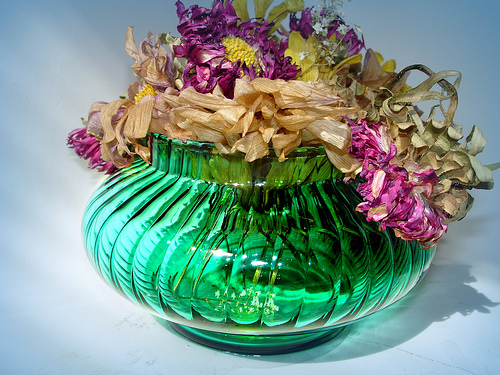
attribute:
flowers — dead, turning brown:
[87, 77, 360, 175]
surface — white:
[2, 126, 497, 371]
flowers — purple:
[182, 6, 299, 88]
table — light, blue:
[0, 188, 79, 364]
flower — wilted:
[59, 96, 142, 181]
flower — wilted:
[176, 2, 291, 92]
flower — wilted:
[339, 111, 435, 252]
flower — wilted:
[125, 30, 190, 120]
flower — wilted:
[298, 16, 365, 96]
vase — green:
[51, 85, 440, 363]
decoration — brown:
[88, 25, 362, 175]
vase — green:
[61, 125, 438, 372]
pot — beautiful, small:
[79, 130, 436, 356]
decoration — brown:
[380, 72, 495, 251]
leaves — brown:
[173, 79, 285, 150]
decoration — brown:
[59, 3, 489, 277]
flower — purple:
[63, 123, 120, 175]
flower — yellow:
[285, 32, 360, 84]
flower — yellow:
[233, 0, 304, 32]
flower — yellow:
[218, 33, 258, 65]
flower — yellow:
[130, 84, 159, 106]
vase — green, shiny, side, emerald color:
[72, 124, 446, 359]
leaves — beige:
[79, 22, 499, 223]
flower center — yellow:
[220, 31, 264, 74]